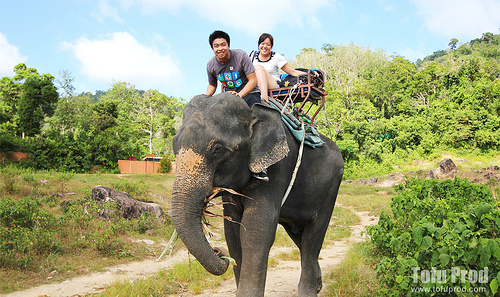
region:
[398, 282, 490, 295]
web site address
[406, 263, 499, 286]
company name in white lettering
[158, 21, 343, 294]
two people sitting on top of baby elephant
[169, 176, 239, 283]
elephant trunk holding foliage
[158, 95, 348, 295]
elephant eating foliage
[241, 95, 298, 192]
small elephant ear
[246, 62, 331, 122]
red seatng on top of elephant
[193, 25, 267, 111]
boy in t-shirt riding baby elephant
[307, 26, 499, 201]
tall green trees and foliage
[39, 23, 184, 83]
one white cloud in light blue sky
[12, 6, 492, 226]
This is during the daytime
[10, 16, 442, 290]
This picture is outside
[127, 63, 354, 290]
This is an elephant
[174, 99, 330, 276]
The elephant is gray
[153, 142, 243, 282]
The elephant's trunk is brown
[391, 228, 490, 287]
This photo is watermarked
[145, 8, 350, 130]
These people are riding an elephant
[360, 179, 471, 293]
These are bushes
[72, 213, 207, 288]
The path is made of dirt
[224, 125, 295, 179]
The elephant's ear is brown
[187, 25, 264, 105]
a man riding on the back of an elephant.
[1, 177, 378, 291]
a dirt road near an elephant.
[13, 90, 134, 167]
a green tree with lots of leaves.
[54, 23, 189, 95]
a white cloud in a blue sky.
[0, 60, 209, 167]
a forest filled with green trees.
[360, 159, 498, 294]
a green bush with lots of leaves.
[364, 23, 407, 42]
a section of blue sky.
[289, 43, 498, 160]
a forest filled with lots of green leaves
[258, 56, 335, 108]
a seat on top of an elephant.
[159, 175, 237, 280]
a small gray elephant trunk.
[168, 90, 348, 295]
A young elephant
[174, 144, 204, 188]
Brown spots on a gray elephant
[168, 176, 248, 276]
An elephant eating hay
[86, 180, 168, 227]
A gray rock in the grass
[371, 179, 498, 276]
Healthy green bushes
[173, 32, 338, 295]
Two people riding on the back of an elephant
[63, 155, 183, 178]
A short red wall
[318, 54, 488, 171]
A row of tall trees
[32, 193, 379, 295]
Dirt paths in the grass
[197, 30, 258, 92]
A man smiling at the camera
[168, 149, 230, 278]
The trunk of an elephant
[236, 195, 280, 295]
Front leg of an elephant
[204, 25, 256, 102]
Man with black hair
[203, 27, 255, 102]
Man wearing a t-shirt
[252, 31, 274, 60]
Woman with a smile on her face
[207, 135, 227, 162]
Eye of an elephant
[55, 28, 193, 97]
White cloud in the sky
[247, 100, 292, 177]
Left ear of an elephant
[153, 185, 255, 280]
Grass in an elephants trunk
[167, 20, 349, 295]
Two people on an elephant